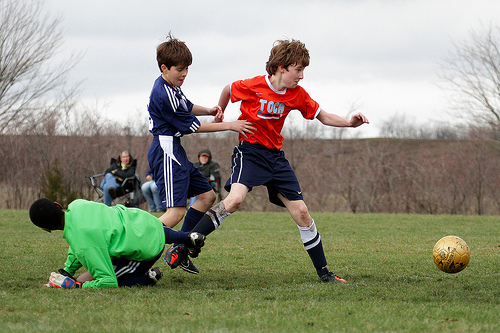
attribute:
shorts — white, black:
[233, 137, 320, 215]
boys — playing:
[53, 3, 393, 293]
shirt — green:
[25, 183, 176, 285]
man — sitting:
[96, 130, 182, 222]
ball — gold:
[413, 210, 483, 278]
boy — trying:
[185, 17, 344, 270]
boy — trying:
[124, 30, 287, 261]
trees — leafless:
[2, 16, 130, 190]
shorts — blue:
[210, 139, 338, 229]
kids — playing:
[81, 30, 358, 268]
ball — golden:
[435, 231, 488, 281]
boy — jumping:
[111, 38, 333, 256]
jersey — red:
[229, 77, 329, 163]